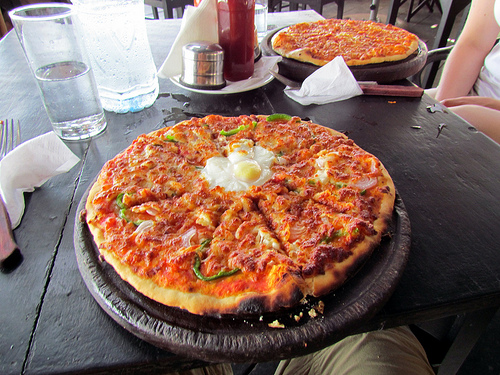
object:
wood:
[75, 20, 421, 315]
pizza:
[84, 111, 396, 317]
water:
[32, 61, 102, 127]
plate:
[72, 164, 412, 359]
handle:
[347, 84, 424, 97]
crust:
[81, 114, 394, 317]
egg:
[199, 140, 277, 192]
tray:
[70, 172, 412, 358]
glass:
[9, 3, 107, 144]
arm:
[435, 0, 498, 102]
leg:
[422, 86, 481, 104]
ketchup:
[216, 1, 256, 82]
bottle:
[215, 0, 255, 83]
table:
[0, 7, 492, 373]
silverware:
[270, 69, 428, 99]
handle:
[352, 81, 424, 100]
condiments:
[174, 3, 261, 92]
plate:
[164, 57, 281, 97]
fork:
[1, 115, 21, 158]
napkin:
[0, 127, 80, 229]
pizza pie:
[80, 110, 398, 317]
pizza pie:
[272, 18, 421, 68]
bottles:
[180, 0, 254, 90]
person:
[424, 1, 498, 146]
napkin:
[285, 54, 362, 107]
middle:
[200, 141, 277, 192]